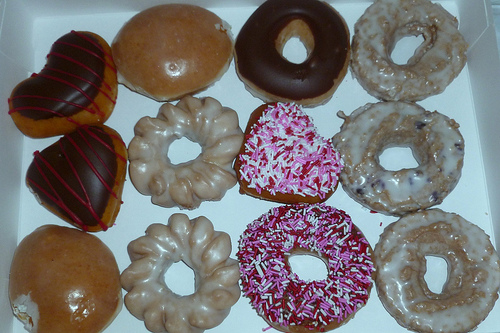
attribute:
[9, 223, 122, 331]
doughnut — glaze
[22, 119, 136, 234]
doughnut — heart-shaped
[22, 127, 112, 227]
glaze — chocolate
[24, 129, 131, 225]
drizzle — red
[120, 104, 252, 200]
doughnut — white 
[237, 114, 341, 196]
doughnuts — heart-shaped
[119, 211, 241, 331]
spiral doughnut — white, glazed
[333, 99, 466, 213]
doughnut — with icing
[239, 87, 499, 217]
doughnut — with white glaze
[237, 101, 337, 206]
doughnut — heart-shaped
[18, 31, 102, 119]
glaze — chocolate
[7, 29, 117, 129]
drizzle — red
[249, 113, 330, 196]
sprinkles — white, pink